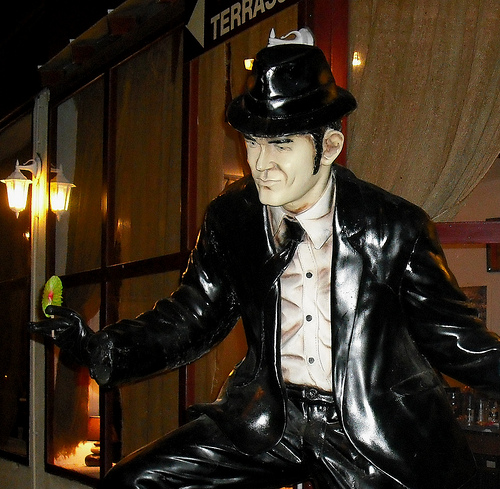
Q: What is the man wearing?
A: A leather suit.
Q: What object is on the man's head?
A: A hat.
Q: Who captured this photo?
A: A photographer.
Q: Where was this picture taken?
A: Near statue.